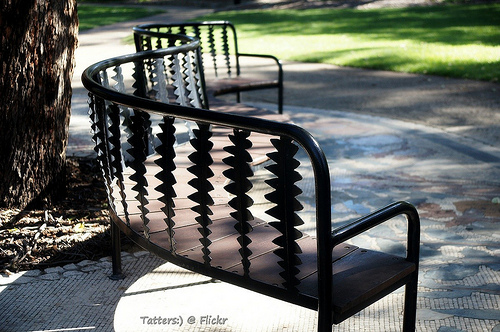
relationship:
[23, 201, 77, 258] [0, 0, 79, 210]
twigs around tree